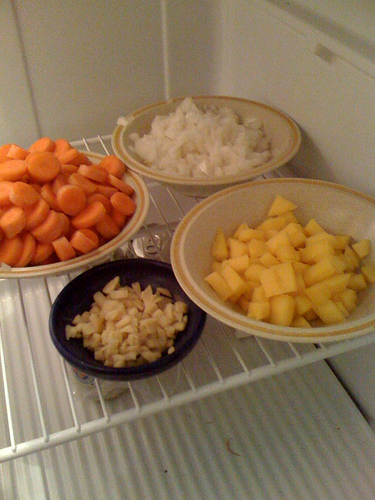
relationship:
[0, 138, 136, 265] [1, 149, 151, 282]
carrots in a bowl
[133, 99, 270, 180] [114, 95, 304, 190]
onions in a bowl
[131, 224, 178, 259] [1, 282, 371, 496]
can on bottom shelf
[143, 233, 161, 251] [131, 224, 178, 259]
tab on can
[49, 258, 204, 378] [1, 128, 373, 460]
bowl on a shelf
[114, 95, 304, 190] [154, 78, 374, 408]
bowl on right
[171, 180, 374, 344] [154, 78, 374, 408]
bowl on right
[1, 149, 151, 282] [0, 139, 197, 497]
bowl on left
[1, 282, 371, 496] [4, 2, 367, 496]
bottom shelf in refrigerator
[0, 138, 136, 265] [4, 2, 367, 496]
carrots in a refrigerator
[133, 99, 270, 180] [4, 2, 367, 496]
onions in a refrigerator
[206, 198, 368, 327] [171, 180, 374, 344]
pineapples in a bowl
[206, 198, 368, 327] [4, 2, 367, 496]
pineapples in a refrigerator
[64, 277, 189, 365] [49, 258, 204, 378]
nuts in a bowl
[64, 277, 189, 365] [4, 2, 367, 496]
nuts in a refrigerator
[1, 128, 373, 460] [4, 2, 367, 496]
shelf in a refrigerator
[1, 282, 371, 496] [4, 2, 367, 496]
bottom shelf of a refrigerator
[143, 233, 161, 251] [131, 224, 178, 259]
tab of a can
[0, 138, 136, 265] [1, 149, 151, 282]
carrots in bowl